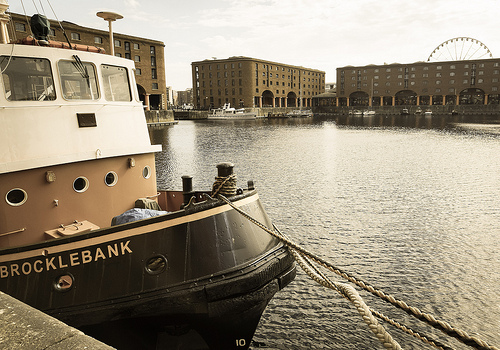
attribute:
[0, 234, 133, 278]
writing — gold, brocklebank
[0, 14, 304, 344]
boat — docked, black, white, motionless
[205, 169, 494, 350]
rope — tied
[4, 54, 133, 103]
windows — glass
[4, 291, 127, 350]
dock — cement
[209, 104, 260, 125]
boat — docked, far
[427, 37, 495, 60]
ferris wheel — far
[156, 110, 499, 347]
water — calm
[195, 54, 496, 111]
buildings — large, rectangular, tan, concrete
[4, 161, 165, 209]
windows — round, small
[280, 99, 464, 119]
boats — docked, white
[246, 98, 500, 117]
wall — cement